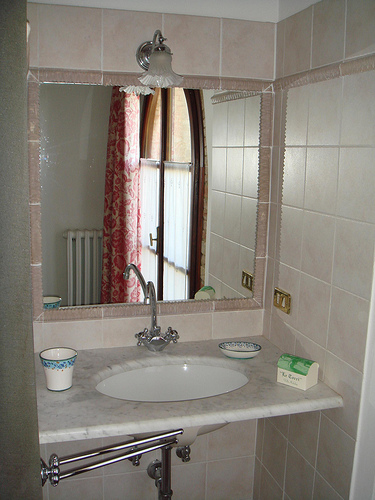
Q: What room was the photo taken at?
A: It was taken at the bathroom.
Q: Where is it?
A: This is at the bathroom.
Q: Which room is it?
A: It is a bathroom.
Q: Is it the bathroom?
A: Yes, it is the bathroom.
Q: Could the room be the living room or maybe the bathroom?
A: It is the bathroom.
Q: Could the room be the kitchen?
A: No, it is the bathroom.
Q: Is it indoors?
A: Yes, it is indoors.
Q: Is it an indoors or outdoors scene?
A: It is indoors.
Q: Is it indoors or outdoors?
A: It is indoors.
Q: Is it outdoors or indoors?
A: It is indoors.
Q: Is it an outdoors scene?
A: No, it is indoors.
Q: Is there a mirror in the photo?
A: Yes, there is a mirror.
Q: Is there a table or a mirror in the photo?
A: Yes, there is a mirror.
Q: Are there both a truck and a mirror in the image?
A: No, there is a mirror but no trucks.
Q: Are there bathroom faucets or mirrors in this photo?
A: Yes, there is a bathroom mirror.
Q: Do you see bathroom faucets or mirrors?
A: Yes, there is a bathroom mirror.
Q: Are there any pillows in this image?
A: No, there are no pillows.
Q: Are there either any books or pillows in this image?
A: No, there are no pillows or books.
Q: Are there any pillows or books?
A: No, there are no pillows or books.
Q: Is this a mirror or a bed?
A: This is a mirror.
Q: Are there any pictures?
A: No, there are no pictures.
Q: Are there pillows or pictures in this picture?
A: No, there are no pictures or pillows.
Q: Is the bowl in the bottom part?
A: Yes, the bowl is in the bottom of the image.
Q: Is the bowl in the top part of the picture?
A: No, the bowl is in the bottom of the image.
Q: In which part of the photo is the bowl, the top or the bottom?
A: The bowl is in the bottom of the image.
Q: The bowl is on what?
A: The bowl is on the counter top.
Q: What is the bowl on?
A: The bowl is on the counter top.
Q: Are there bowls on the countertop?
A: Yes, there is a bowl on the countertop.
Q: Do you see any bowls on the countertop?
A: Yes, there is a bowl on the countertop.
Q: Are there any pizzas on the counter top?
A: No, there is a bowl on the counter top.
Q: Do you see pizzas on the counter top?
A: No, there is a bowl on the counter top.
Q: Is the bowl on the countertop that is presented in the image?
A: Yes, the bowl is on the countertop.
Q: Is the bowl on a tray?
A: No, the bowl is on the countertop.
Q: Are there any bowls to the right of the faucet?
A: Yes, there is a bowl to the right of the faucet.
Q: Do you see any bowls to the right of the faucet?
A: Yes, there is a bowl to the right of the faucet.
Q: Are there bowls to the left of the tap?
A: No, the bowl is to the right of the tap.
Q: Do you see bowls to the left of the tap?
A: No, the bowl is to the right of the tap.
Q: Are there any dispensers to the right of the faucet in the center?
A: No, there is a bowl to the right of the tap.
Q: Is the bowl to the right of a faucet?
A: Yes, the bowl is to the right of a faucet.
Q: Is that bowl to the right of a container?
A: No, the bowl is to the right of a faucet.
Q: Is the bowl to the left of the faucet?
A: No, the bowl is to the right of the faucet.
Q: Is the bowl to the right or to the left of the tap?
A: The bowl is to the right of the tap.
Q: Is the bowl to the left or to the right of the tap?
A: The bowl is to the right of the tap.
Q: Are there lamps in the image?
A: Yes, there is a lamp.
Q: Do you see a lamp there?
A: Yes, there is a lamp.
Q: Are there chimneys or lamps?
A: Yes, there is a lamp.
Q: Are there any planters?
A: No, there are no planters.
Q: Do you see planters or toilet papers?
A: No, there are no planters or toilet papers.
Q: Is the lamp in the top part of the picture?
A: Yes, the lamp is in the top of the image.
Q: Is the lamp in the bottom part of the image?
A: No, the lamp is in the top of the image.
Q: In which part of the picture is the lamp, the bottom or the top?
A: The lamp is in the top of the image.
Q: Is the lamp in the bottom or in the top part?
A: The lamp is in the top of the image.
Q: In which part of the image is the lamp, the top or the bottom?
A: The lamp is in the top of the image.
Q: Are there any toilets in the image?
A: No, there are no toilets.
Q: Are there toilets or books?
A: No, there are no toilets or books.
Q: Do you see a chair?
A: No, there are no chairs.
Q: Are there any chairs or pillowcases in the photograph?
A: No, there are no chairs or pillowcases.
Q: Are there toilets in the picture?
A: No, there are no toilets.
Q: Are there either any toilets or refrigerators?
A: No, there are no toilets or refrigerators.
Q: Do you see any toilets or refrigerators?
A: No, there are no toilets or refrigerators.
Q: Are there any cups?
A: Yes, there is a cup.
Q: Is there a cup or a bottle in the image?
A: Yes, there is a cup.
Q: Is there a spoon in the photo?
A: No, there are no spoons.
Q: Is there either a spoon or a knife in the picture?
A: No, there are no spoons or knives.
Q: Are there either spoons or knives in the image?
A: No, there are no spoons or knives.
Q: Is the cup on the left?
A: Yes, the cup is on the left of the image.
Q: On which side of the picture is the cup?
A: The cup is on the left of the image.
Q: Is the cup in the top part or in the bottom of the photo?
A: The cup is in the bottom of the image.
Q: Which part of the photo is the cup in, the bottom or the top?
A: The cup is in the bottom of the image.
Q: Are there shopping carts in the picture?
A: No, there are no shopping carts.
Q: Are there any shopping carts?
A: No, there are no shopping carts.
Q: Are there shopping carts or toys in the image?
A: No, there are no shopping carts or toys.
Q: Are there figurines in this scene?
A: No, there are no figurines.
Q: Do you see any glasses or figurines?
A: No, there are no figurines or glasses.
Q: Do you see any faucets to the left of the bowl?
A: Yes, there is a faucet to the left of the bowl.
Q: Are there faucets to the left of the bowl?
A: Yes, there is a faucet to the left of the bowl.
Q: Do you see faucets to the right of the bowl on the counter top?
A: No, the faucet is to the left of the bowl.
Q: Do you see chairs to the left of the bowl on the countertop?
A: No, there is a faucet to the left of the bowl.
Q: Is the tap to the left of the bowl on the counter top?
A: Yes, the tap is to the left of the bowl.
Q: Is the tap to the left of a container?
A: No, the tap is to the left of the bowl.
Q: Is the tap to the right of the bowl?
A: No, the tap is to the left of the bowl.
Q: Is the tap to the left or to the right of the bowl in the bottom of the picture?
A: The tap is to the left of the bowl.